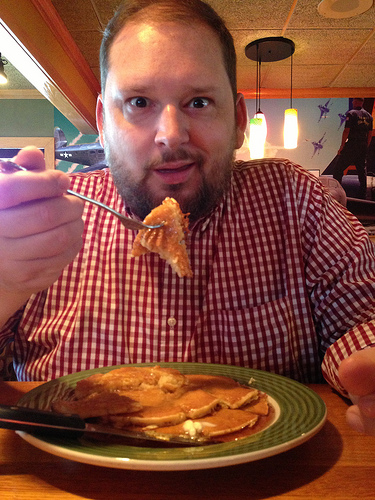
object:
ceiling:
[54, 2, 374, 89]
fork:
[0, 158, 165, 232]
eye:
[183, 93, 214, 109]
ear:
[235, 92, 248, 149]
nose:
[154, 103, 190, 151]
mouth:
[151, 159, 197, 184]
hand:
[0, 142, 87, 308]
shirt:
[0, 158, 374, 399]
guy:
[2, 3, 375, 428]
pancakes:
[51, 365, 269, 436]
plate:
[12, 362, 327, 471]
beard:
[104, 127, 238, 224]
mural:
[259, 94, 375, 196]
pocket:
[203, 294, 297, 370]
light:
[283, 108, 300, 150]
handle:
[0, 407, 84, 441]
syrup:
[209, 424, 255, 445]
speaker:
[317, 0, 375, 18]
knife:
[1, 400, 166, 445]